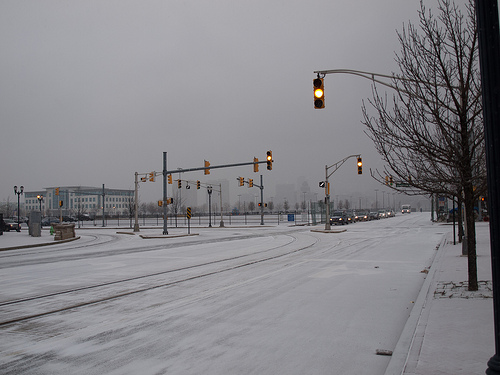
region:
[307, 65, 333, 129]
Traffic signal glowing yellow signal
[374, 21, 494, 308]
Tree without leaves indicating winter season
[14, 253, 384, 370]
Roads spread with ice during the winter season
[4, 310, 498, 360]
Pavement besides the ice spread road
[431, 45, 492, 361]
Trees standing inside the pavement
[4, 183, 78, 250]
Tall light poles with two lamps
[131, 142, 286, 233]
Traffic signal with display board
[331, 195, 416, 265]
Vehicles forming a queue in a traffic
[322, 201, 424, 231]
Motor vehicles headlight on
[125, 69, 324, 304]
Beautiful scene of the sky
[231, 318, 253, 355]
part of a snow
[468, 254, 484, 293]
[art pf a stem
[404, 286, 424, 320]
part of an eged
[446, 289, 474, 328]
part of a poath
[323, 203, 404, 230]
cars at the traffic light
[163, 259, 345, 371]
snow on the street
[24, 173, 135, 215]
building behind trees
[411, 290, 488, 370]
snow on the sidewalk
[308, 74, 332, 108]
yellow light on a pole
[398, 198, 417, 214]
bus approaching other cars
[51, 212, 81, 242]
Bin on the curb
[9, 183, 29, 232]
Street lamp on the corner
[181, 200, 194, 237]
traffic sign on the corner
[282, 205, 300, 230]
blue bin on the sidewalk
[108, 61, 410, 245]
several traffic lights at a intersection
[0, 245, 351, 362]
a street covered with snow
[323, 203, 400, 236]
several cars stopped at a traffic light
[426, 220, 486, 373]
sidewalk covered with snow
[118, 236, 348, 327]
tracks in the snow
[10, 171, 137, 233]
a tall building with several levels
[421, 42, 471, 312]
several trees with no leaves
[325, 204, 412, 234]
several cars with headlights on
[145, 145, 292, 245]
a pole with traffic lights attached to it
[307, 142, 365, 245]
a pole in the middle of a intersection